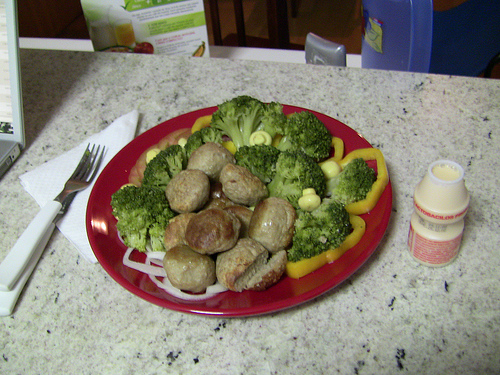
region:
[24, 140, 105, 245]
silver fork kept in the napkin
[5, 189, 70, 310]
plastic handle of the fork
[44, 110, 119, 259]
white color napkin kept in a table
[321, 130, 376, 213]
yellow color capsicum in the plate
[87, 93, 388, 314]
red color circle shape plate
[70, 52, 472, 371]
dining table with stone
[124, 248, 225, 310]
chopped onion in the plate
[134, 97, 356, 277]
food items ready to eat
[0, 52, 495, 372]
gray stone table with black specks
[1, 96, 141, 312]
knife and fork over folded napkin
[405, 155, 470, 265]
small open plastic container of white liquid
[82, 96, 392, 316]
red plate with meat and vegetables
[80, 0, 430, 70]
package and bottles behind table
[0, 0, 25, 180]
blue edge of open device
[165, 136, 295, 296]
browned meatballs in pile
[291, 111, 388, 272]
broccoli in open slices of yellow pepper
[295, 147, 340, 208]
yellow button mushrooms on top of green vegetable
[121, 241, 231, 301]
thin slices of onion under meatball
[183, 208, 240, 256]
brown colored meat ball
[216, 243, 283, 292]
brown colored meat ball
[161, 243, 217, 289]
brown colored meat ball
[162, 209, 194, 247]
brown colored meat ball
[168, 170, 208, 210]
brown colored meat ball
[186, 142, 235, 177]
brown colored meat ball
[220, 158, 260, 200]
brown colored meat ball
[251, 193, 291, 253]
brown colored meat ball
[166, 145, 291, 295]
brown colored meat balls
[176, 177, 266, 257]
Meatballs on the red plate.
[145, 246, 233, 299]
Onions under the meatballs.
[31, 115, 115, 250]
A white napkin on the table.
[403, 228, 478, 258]
The jug has red writing.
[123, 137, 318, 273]
Food on the plate.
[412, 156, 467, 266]
LITTLE DRINK FOR A MEAL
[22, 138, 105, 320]
WHITE HANDLED UTENSILS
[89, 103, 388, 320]
RED PLATE WILLED WITH FOOD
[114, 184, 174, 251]
GREEN BROCCOLI CROWN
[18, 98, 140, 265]
TRIANGULAR FOLDER PAPER NAPKIN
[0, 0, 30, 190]
CORNER OF A LAPTOP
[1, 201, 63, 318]
PLASTIC WHITE HANDLE FOR FORKS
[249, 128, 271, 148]
LITTLE OFF WHITE MUSHROOM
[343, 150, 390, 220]
SLICED COOKED YELLOW BELLPEPPER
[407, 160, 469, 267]
the small probiotic drink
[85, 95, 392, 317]
the food on the plate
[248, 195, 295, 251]
the meatball is cooked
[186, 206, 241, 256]
the meatball is brown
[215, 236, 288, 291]
the meatball is cut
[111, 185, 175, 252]
the broccoli is green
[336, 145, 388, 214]
the bell pepper is yellow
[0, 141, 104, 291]
the fork has a white handle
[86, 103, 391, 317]
the plate is red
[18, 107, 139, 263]
the napkin is white